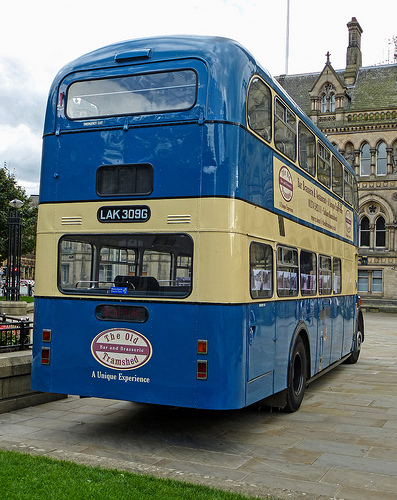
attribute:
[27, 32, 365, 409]
bus — double decker, blue, cream, large, old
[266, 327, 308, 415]
tire — black, round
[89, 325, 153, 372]
logo — purple, white, oval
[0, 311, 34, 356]
fence — black, short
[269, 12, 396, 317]
building — old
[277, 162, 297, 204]
logo — oval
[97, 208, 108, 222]
letter — white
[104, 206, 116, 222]
letter — white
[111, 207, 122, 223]
letter — white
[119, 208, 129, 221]
number — white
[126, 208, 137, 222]
number — white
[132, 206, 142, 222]
number — white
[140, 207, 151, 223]
letter — white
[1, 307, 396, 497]
parking lot — flagstone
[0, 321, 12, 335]
flower — pink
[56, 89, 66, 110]
handle — red